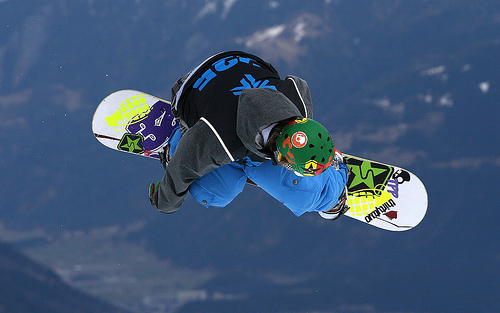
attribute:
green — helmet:
[316, 162, 318, 164]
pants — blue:
[202, 185, 332, 204]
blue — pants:
[259, 180, 292, 198]